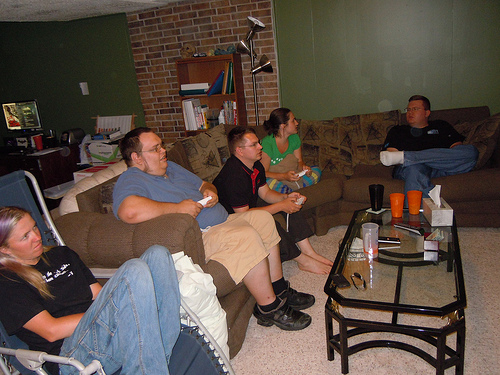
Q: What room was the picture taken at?
A: It was taken at the living room.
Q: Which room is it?
A: It is a living room.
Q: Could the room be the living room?
A: Yes, it is the living room.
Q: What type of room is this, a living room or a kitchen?
A: It is a living room.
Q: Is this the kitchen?
A: No, it is the living room.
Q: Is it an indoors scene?
A: Yes, it is indoors.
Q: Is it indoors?
A: Yes, it is indoors.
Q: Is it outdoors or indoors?
A: It is indoors.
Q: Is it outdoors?
A: No, it is indoors.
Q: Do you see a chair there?
A: Yes, there is a chair.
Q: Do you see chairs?
A: Yes, there is a chair.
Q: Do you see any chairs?
A: Yes, there is a chair.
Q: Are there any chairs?
A: Yes, there is a chair.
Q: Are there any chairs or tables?
A: Yes, there is a chair.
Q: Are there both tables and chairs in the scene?
A: Yes, there are both a chair and a table.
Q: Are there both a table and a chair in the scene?
A: Yes, there are both a chair and a table.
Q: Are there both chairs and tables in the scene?
A: Yes, there are both a chair and a table.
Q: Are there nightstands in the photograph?
A: No, there are no nightstands.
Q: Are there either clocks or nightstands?
A: No, there are no nightstands or clocks.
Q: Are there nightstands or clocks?
A: No, there are no nightstands or clocks.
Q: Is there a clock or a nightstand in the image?
A: No, there are no nightstands or clocks.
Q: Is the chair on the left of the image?
A: Yes, the chair is on the left of the image.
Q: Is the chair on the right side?
A: No, the chair is on the left of the image.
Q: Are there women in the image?
A: Yes, there is a woman.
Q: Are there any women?
A: Yes, there is a woman.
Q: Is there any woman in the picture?
A: Yes, there is a woman.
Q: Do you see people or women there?
A: Yes, there is a woman.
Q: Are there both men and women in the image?
A: Yes, there are both a woman and a man.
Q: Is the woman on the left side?
A: Yes, the woman is on the left of the image.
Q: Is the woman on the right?
A: No, the woman is on the left of the image.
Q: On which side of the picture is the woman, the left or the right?
A: The woman is on the left of the image.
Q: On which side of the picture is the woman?
A: The woman is on the left of the image.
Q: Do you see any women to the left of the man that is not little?
A: Yes, there is a woman to the left of the man.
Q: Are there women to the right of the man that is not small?
A: No, the woman is to the left of the man.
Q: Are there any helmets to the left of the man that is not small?
A: No, there is a woman to the left of the man.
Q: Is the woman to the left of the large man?
A: Yes, the woman is to the left of the man.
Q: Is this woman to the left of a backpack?
A: No, the woman is to the left of the man.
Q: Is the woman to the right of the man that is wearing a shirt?
A: No, the woman is to the left of the man.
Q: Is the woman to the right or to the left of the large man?
A: The woman is to the left of the man.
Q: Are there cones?
A: No, there are no cones.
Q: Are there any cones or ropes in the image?
A: No, there are no cones or ropes.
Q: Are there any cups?
A: Yes, there is a cup.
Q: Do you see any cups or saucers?
A: Yes, there is a cup.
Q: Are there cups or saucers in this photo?
A: Yes, there is a cup.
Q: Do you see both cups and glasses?
A: Yes, there are both a cup and glasses.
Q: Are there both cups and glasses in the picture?
A: Yes, there are both a cup and glasses.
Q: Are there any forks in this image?
A: No, there are no forks.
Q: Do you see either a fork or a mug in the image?
A: No, there are no forks or mugs.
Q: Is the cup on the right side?
A: Yes, the cup is on the right of the image.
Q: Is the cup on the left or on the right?
A: The cup is on the right of the image.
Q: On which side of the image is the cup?
A: The cup is on the right of the image.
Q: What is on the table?
A: The cup is on the table.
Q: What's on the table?
A: The cup is on the table.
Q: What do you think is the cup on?
A: The cup is on the table.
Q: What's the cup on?
A: The cup is on the table.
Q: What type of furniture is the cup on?
A: The cup is on the table.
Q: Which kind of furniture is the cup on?
A: The cup is on the table.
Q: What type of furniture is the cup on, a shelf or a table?
A: The cup is on a table.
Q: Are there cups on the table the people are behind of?
A: Yes, there is a cup on the table.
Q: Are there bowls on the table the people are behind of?
A: No, there is a cup on the table.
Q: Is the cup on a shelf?
A: No, the cup is on the table.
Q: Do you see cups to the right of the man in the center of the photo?
A: Yes, there is a cup to the right of the man.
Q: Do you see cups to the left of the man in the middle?
A: No, the cup is to the right of the man.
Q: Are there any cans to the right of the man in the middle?
A: No, there is a cup to the right of the man.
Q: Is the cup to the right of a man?
A: Yes, the cup is to the right of a man.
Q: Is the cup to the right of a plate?
A: No, the cup is to the right of a man.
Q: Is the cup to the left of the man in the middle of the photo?
A: No, the cup is to the right of the man.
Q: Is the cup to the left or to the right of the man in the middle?
A: The cup is to the right of the man.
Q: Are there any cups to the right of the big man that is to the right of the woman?
A: Yes, there is a cup to the right of the man.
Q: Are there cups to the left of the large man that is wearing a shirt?
A: No, the cup is to the right of the man.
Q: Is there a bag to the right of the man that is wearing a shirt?
A: No, there is a cup to the right of the man.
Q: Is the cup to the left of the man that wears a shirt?
A: No, the cup is to the right of the man.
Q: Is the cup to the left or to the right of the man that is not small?
A: The cup is to the right of the man.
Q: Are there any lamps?
A: Yes, there is a lamp.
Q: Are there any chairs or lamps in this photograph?
A: Yes, there is a lamp.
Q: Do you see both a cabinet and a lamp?
A: No, there is a lamp but no cabinets.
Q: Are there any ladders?
A: No, there are no ladders.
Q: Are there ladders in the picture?
A: No, there are no ladders.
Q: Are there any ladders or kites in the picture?
A: No, there are no ladders or kites.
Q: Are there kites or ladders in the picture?
A: No, there are no ladders or kites.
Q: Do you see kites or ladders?
A: No, there are no ladders or kites.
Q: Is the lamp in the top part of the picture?
A: Yes, the lamp is in the top of the image.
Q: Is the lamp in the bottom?
A: No, the lamp is in the top of the image.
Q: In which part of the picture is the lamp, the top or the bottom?
A: The lamp is in the top of the image.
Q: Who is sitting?
A: The people are sitting.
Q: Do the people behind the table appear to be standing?
A: No, the people are sitting.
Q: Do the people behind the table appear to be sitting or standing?
A: The people are sitting.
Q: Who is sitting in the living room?
A: The people are sitting in the living room.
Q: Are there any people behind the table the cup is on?
A: Yes, there are people behind the table.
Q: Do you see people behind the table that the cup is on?
A: Yes, there are people behind the table.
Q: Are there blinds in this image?
A: No, there are no blinds.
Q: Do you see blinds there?
A: No, there are no blinds.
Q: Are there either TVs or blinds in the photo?
A: No, there are no blinds or tvs.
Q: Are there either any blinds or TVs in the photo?
A: No, there are no blinds or tvs.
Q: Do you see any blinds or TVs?
A: No, there are no blinds or tvs.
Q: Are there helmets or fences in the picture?
A: No, there are no fences or helmets.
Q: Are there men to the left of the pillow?
A: Yes, there is a man to the left of the pillow.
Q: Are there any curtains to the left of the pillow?
A: No, there is a man to the left of the pillow.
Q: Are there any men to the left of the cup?
A: Yes, there is a man to the left of the cup.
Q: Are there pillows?
A: Yes, there is a pillow.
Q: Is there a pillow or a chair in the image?
A: Yes, there is a pillow.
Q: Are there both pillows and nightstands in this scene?
A: No, there is a pillow but no nightstands.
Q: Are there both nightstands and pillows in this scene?
A: No, there is a pillow but no nightstands.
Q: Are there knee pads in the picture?
A: No, there are no knee pads.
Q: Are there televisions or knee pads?
A: No, there are no knee pads or televisions.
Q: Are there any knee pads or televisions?
A: No, there are no knee pads or televisions.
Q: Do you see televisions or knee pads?
A: No, there are no knee pads or televisions.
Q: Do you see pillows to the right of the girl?
A: Yes, there is a pillow to the right of the girl.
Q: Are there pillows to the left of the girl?
A: No, the pillow is to the right of the girl.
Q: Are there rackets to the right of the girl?
A: No, there is a pillow to the right of the girl.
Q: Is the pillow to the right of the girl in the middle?
A: Yes, the pillow is to the right of the girl.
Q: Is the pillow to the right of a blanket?
A: No, the pillow is to the right of the girl.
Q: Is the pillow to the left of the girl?
A: No, the pillow is to the right of the girl.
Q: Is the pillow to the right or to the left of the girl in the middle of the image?
A: The pillow is to the right of the girl.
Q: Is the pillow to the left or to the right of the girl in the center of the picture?
A: The pillow is to the right of the girl.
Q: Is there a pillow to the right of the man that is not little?
A: Yes, there is a pillow to the right of the man.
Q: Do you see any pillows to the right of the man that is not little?
A: Yes, there is a pillow to the right of the man.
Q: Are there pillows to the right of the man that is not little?
A: Yes, there is a pillow to the right of the man.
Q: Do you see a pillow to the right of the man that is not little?
A: Yes, there is a pillow to the right of the man.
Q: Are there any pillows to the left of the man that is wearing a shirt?
A: No, the pillow is to the right of the man.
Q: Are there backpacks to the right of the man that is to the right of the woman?
A: No, there is a pillow to the right of the man.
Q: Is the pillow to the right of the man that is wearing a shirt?
A: Yes, the pillow is to the right of the man.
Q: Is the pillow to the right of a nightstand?
A: No, the pillow is to the right of the man.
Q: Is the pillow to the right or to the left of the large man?
A: The pillow is to the right of the man.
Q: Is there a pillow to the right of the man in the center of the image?
A: Yes, there is a pillow to the right of the man.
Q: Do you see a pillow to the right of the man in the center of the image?
A: Yes, there is a pillow to the right of the man.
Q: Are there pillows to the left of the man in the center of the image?
A: No, the pillow is to the right of the man.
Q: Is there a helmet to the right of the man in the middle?
A: No, there is a pillow to the right of the man.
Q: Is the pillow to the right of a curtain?
A: No, the pillow is to the right of a man.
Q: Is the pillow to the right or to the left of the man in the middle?
A: The pillow is to the right of the man.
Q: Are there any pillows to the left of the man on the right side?
A: Yes, there is a pillow to the left of the man.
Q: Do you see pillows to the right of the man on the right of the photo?
A: No, the pillow is to the left of the man.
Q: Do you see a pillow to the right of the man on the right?
A: No, the pillow is to the left of the man.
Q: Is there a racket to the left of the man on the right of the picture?
A: No, there is a pillow to the left of the man.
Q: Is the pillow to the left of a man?
A: Yes, the pillow is to the left of a man.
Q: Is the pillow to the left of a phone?
A: No, the pillow is to the left of a man.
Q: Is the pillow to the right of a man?
A: No, the pillow is to the left of a man.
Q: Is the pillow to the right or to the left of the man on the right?
A: The pillow is to the left of the man.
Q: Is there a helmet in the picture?
A: No, there are no helmets.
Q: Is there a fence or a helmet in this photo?
A: No, there are no helmets or fences.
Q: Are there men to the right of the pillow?
A: Yes, there is a man to the right of the pillow.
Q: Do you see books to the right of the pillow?
A: No, there is a man to the right of the pillow.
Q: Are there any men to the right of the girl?
A: Yes, there is a man to the right of the girl.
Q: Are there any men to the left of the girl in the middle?
A: No, the man is to the right of the girl.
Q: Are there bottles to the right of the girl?
A: No, there is a man to the right of the girl.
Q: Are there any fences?
A: No, there are no fences.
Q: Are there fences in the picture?
A: No, there are no fences.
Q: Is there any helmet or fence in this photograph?
A: No, there are no fences or helmets.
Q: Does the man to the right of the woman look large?
A: Yes, the man is large.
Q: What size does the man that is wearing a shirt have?
A: The man has large size.